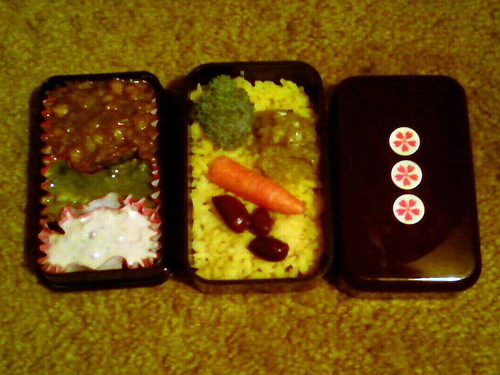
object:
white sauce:
[28, 192, 154, 271]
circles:
[387, 192, 426, 224]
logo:
[389, 189, 425, 225]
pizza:
[201, 154, 310, 217]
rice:
[191, 79, 317, 280]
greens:
[201, 75, 257, 147]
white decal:
[385, 156, 428, 190]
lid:
[334, 72, 480, 284]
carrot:
[207, 157, 311, 216]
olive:
[202, 193, 251, 233]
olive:
[250, 206, 272, 236]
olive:
[246, 236, 288, 261]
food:
[40, 195, 160, 272]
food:
[38, 154, 155, 210]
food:
[38, 74, 158, 170]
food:
[192, 74, 257, 153]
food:
[204, 150, 311, 215]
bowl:
[25, 65, 175, 292]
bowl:
[176, 59, 338, 297]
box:
[329, 67, 480, 295]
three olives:
[202, 192, 296, 263]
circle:
[388, 125, 420, 155]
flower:
[386, 125, 422, 155]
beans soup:
[50, 80, 155, 168]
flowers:
[389, 193, 428, 227]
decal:
[389, 126, 418, 157]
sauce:
[47, 172, 154, 201]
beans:
[41, 82, 163, 192]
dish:
[31, 73, 176, 295]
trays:
[18, 58, 489, 294]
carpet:
[145, 286, 436, 338]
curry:
[193, 73, 257, 151]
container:
[26, 73, 172, 285]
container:
[167, 51, 332, 290]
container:
[326, 73, 483, 292]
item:
[200, 79, 256, 148]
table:
[5, 2, 497, 370]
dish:
[168, 62, 328, 294]